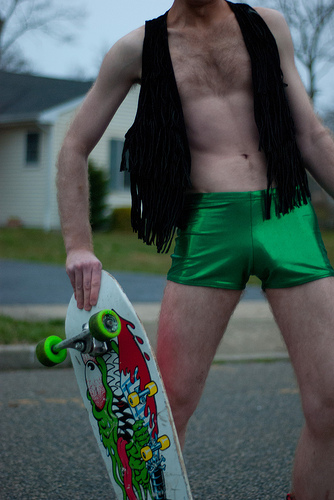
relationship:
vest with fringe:
[113, 3, 323, 250] [117, 103, 311, 248]